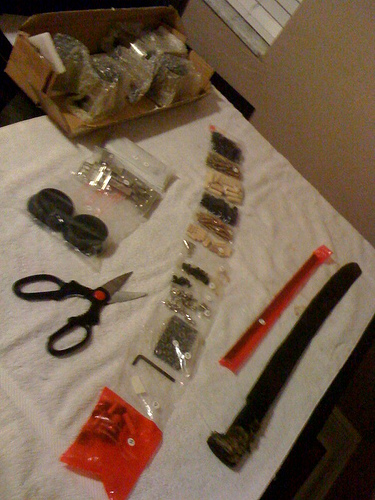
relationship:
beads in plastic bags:
[161, 330, 213, 358] [108, 351, 183, 413]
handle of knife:
[189, 414, 287, 467] [193, 250, 367, 470]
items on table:
[33, 161, 140, 340] [12, 131, 373, 463]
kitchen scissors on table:
[14, 266, 136, 353] [8, 108, 370, 489]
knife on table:
[204, 253, 367, 485] [5, 155, 244, 495]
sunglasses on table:
[34, 181, 106, 266] [13, 82, 355, 489]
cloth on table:
[243, 155, 322, 257] [4, 132, 325, 498]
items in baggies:
[48, 22, 195, 104] [44, 24, 196, 101]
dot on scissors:
[93, 285, 105, 302] [14, 268, 142, 355]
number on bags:
[119, 429, 141, 446] [64, 389, 171, 498]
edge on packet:
[107, 389, 158, 427] [60, 387, 162, 499]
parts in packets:
[170, 172, 225, 322] [130, 134, 249, 387]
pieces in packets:
[145, 146, 220, 375] [130, 134, 249, 387]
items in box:
[53, 29, 194, 94] [17, 2, 211, 126]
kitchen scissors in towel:
[13, 269, 149, 356] [10, 106, 361, 490]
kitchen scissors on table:
[13, 269, 149, 356] [8, 108, 370, 489]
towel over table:
[1, 84, 369, 495] [8, 108, 370, 489]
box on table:
[2, 4, 216, 141] [8, 108, 370, 489]